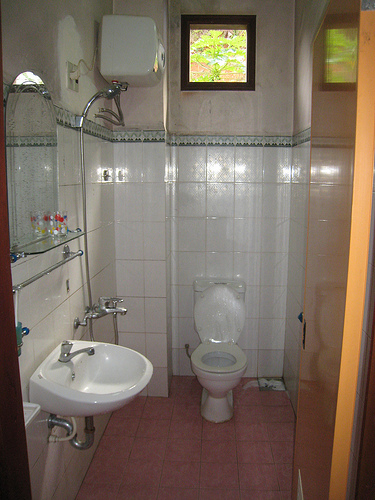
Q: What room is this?
A: Bathroom.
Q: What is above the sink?
A: Mirror.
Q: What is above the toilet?
A: Window.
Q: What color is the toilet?
A: White.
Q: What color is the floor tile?
A: Reddish brown floor tiles.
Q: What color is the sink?
A: White.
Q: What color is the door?
A: Brown.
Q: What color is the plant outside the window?
A: Green.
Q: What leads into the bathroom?
A: A door.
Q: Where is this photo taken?
A: In a bathroom.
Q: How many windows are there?
A: One.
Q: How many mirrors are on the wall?
A: One.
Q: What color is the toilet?
A: White.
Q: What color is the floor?
A: Pink.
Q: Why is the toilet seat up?
A: Because the owner of the home left the seat up.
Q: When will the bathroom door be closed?
A: When a man or woman comes to use the bathroom.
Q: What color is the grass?
A: Green.